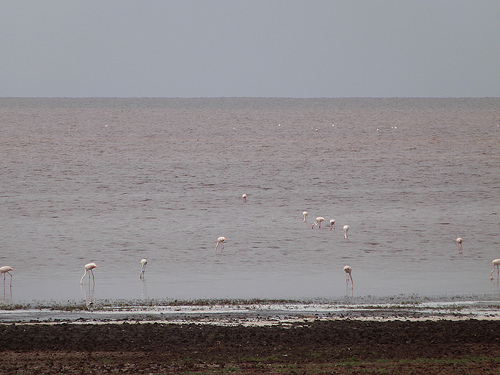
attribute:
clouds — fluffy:
[300, 16, 397, 56]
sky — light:
[83, 23, 210, 69]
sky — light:
[168, 0, 336, 56]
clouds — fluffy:
[249, 36, 359, 79]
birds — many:
[204, 59, 431, 246]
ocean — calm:
[97, 124, 327, 194]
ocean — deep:
[88, 135, 277, 185]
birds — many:
[164, 166, 414, 247]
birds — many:
[146, 173, 378, 240]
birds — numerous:
[220, 168, 440, 251]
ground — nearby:
[120, 302, 363, 351]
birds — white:
[191, 145, 396, 262]